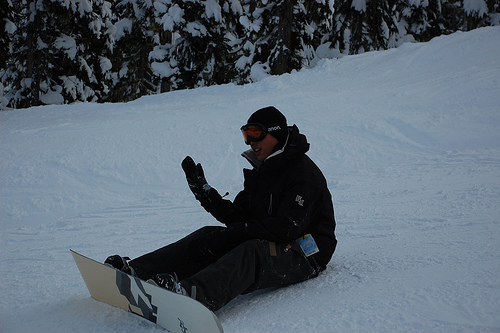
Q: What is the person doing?
A: Snowboarding.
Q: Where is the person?
A: On a slope.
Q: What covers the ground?
A: Snow.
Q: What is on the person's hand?
A: Glove.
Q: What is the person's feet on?
A: Snowboard.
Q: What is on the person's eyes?
A: Goggles.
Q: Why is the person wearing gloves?
A: It is cold.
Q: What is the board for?
A: To snowboard.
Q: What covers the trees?
A: Snow.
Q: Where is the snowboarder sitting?
A: Ground.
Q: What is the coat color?
A: Black.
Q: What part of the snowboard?
A: Bottom.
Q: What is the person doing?
A: Snowboarding.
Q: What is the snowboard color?
A: White.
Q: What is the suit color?
A: Dark.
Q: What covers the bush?
A: Snow.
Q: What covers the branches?
A: Snow.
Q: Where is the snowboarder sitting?
A: Snow.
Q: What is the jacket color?
A: Black.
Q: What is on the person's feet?
A: A snowboard.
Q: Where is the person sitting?
A: In the snow.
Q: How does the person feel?
A: Cold.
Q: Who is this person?
A: A snowboarder.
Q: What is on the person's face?
A: Goggles.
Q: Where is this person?
A: On a mountain.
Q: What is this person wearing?
A: A snowsuit.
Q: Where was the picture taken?
A: A ski slope.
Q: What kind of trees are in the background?
A: Pine trees.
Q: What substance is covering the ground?
A: Snow.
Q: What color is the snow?
A: White.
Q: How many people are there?
A: One.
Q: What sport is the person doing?
A: Snowboarding.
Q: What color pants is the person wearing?
A: Black.